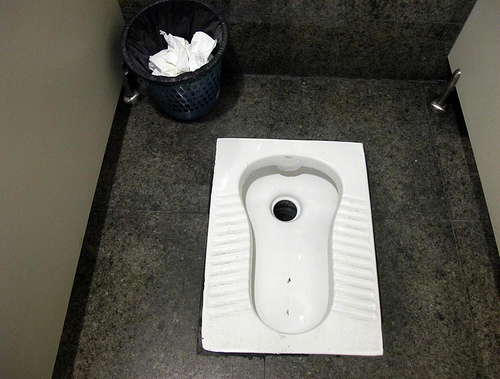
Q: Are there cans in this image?
A: Yes, there is a can.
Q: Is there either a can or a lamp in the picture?
A: Yes, there is a can.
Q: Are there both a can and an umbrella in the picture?
A: No, there is a can but no umbrellas.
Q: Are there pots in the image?
A: No, there are no pots.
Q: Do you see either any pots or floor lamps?
A: No, there are no pots or floor lamps.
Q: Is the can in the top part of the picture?
A: Yes, the can is in the top of the image.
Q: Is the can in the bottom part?
A: No, the can is in the top of the image.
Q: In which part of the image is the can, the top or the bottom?
A: The can is in the top of the image.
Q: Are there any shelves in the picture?
A: No, there are no shelves.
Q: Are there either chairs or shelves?
A: No, there are no shelves or chairs.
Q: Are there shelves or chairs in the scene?
A: No, there are no shelves or chairs.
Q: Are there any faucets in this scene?
A: No, there are no faucets.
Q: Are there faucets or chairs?
A: No, there are no faucets or chairs.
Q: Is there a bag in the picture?
A: Yes, there is a bag.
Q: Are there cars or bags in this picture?
A: Yes, there is a bag.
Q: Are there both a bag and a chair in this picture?
A: No, there is a bag but no chairs.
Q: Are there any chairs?
A: No, there are no chairs.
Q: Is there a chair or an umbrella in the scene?
A: No, there are no chairs or umbrellas.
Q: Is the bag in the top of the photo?
A: Yes, the bag is in the top of the image.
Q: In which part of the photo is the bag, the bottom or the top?
A: The bag is in the top of the image.